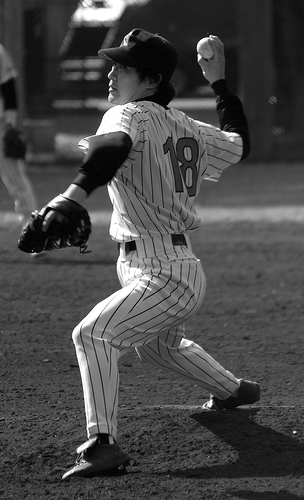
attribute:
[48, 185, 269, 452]
baseball uniform — striped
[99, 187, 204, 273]
shirt — striped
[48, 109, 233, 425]
uniform — stripes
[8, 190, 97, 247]
glove — black, leather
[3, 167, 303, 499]
dirt — dry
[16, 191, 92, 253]
glove — baseball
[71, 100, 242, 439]
uniform — striped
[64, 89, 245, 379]
uniform — striped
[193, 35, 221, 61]
baseball — white, round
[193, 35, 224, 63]
baseball — white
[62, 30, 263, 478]
pitcher — black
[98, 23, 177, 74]
hat — black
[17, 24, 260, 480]
man — black hair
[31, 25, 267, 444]
player — baseball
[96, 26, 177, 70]
hat — black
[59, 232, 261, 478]
pants — pinstriped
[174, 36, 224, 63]
ball — baseball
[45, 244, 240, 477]
pants — striped